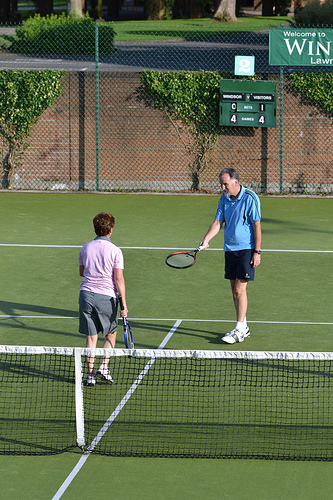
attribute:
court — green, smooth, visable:
[76, 181, 184, 315]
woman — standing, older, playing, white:
[67, 212, 141, 328]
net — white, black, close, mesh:
[154, 345, 266, 457]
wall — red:
[112, 100, 170, 168]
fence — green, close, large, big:
[128, 156, 205, 192]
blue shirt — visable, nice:
[215, 188, 263, 250]